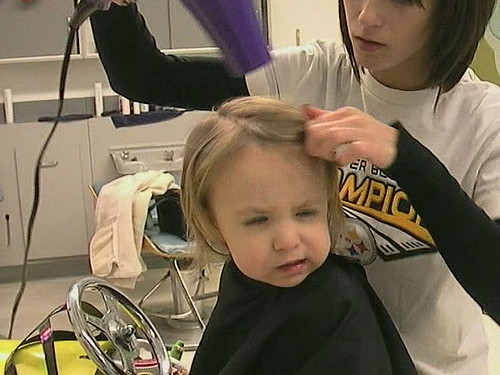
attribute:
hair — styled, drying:
[179, 92, 359, 282]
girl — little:
[114, 74, 483, 375]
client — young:
[157, 135, 419, 375]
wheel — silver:
[66, 245, 173, 373]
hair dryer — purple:
[225, 50, 266, 95]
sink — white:
[108, 119, 190, 185]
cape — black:
[199, 240, 419, 375]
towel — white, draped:
[76, 152, 179, 284]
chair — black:
[77, 175, 217, 331]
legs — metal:
[143, 266, 224, 316]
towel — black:
[183, 245, 411, 375]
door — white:
[9, 138, 99, 264]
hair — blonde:
[162, 117, 359, 267]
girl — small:
[139, 110, 421, 375]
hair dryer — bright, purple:
[219, 50, 251, 129]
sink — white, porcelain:
[105, 137, 191, 192]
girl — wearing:
[135, 90, 416, 323]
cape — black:
[182, 232, 419, 375]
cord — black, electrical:
[11, 67, 79, 353]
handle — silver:
[35, 160, 67, 169]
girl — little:
[155, 90, 416, 375]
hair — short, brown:
[166, 119, 352, 289]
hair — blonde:
[158, 78, 360, 259]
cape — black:
[188, 251, 419, 372]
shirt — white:
[242, 36, 483, 373]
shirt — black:
[83, 1, 253, 113]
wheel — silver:
[64, 272, 174, 372]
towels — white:
[85, 167, 175, 293]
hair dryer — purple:
[179, 0, 278, 79]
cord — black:
[5, 29, 75, 340]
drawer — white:
[12, 145, 90, 261]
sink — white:
[104, 139, 194, 173]